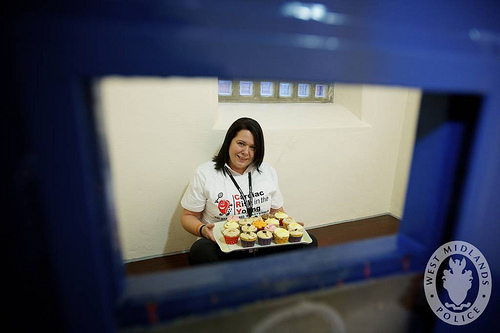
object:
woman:
[179, 116, 320, 267]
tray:
[210, 212, 314, 254]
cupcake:
[221, 228, 240, 244]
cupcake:
[271, 226, 290, 242]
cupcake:
[239, 223, 257, 232]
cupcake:
[273, 209, 288, 218]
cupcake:
[255, 228, 273, 246]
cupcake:
[287, 228, 305, 243]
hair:
[210, 116, 268, 177]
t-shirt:
[180, 158, 287, 232]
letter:
[234, 194, 240, 200]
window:
[87, 57, 500, 302]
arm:
[179, 165, 205, 236]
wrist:
[198, 220, 206, 239]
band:
[199, 222, 221, 239]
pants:
[183, 228, 329, 268]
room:
[90, 75, 424, 279]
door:
[328, 270, 412, 331]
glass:
[120, 204, 166, 231]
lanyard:
[225, 164, 256, 216]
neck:
[228, 161, 253, 173]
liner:
[260, 238, 269, 243]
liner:
[294, 237, 300, 240]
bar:
[232, 82, 240, 93]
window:
[217, 80, 339, 105]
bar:
[309, 84, 315, 97]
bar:
[292, 82, 298, 98]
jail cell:
[319, 141, 398, 243]